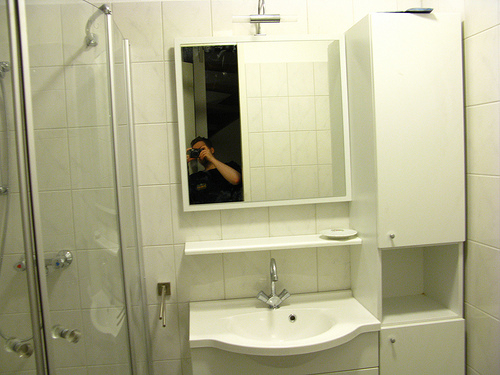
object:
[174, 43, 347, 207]
mirror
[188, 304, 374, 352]
sink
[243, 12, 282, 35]
light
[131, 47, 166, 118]
tile wall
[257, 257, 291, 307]
faucet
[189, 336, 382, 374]
drawer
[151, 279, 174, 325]
towel rod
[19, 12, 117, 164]
doors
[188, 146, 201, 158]
camera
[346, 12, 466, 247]
cupboard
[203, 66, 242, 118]
reflection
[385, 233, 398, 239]
cabinet handle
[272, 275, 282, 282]
spout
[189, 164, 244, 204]
shirt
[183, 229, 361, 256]
counter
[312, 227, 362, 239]
soap dish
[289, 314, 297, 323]
hole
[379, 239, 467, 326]
cabinets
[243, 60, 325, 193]
wall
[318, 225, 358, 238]
soap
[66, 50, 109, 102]
glass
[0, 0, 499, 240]
bathroom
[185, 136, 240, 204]
man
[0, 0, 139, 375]
shower